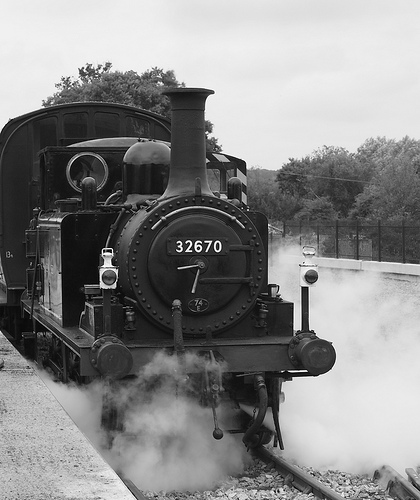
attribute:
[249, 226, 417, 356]
smoke — white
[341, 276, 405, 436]
smoke — white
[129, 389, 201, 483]
smoke — white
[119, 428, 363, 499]
train track — steel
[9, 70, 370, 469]
train — steel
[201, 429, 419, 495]
track — rust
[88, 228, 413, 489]
smoke — white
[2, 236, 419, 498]
smoke — white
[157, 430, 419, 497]
track — steel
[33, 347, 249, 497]
smoke — white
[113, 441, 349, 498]
track — steel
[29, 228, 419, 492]
smoke — white